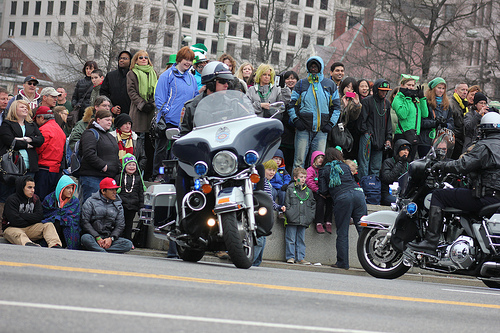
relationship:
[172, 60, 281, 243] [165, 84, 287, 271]
man rides motorcycle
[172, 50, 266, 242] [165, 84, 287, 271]
man on motorcycle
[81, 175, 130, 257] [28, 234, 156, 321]
man sitting on road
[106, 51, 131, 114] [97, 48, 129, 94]
man wearing black coat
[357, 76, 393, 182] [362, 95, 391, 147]
man wearing sweatshirt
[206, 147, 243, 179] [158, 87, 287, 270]
headlight on motorbike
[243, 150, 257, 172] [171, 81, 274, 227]
headlights on motorcycle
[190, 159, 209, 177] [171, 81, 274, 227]
light on motorcycle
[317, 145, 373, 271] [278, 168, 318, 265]
woman taking care of boy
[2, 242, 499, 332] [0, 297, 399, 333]
pavement has line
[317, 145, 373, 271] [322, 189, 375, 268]
woman wearing pants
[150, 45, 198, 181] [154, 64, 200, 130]
woman wearing coat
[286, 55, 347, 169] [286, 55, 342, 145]
man wearing coat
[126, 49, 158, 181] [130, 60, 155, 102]
woman wearing a green scarf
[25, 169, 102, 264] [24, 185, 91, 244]
man with blanket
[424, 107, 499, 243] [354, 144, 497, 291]
police officer on motorbike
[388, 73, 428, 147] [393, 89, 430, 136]
girl wearing coat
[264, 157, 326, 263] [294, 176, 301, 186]
boy wearing paint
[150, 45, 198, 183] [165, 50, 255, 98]
woman wearing a scarf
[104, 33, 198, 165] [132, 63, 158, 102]
woman wearing a green scarf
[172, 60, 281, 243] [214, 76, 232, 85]
man wearing sunglasses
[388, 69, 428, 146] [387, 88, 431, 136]
girl wearing a green coat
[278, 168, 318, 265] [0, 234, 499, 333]
boy on road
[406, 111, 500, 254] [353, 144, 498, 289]
police officer on a motorbike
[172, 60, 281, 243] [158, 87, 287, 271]
man on a motorbike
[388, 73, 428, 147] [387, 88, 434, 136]
girl in a green coat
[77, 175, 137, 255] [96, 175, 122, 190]
man in a cap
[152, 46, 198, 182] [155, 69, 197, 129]
boy wearing coat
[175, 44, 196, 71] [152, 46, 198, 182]
head on boy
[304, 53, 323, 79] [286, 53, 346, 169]
hood on man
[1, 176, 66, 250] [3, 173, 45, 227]
man wearing sweatshirt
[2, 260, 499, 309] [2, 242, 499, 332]
line on pavement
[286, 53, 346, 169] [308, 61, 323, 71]
man wearing glasses